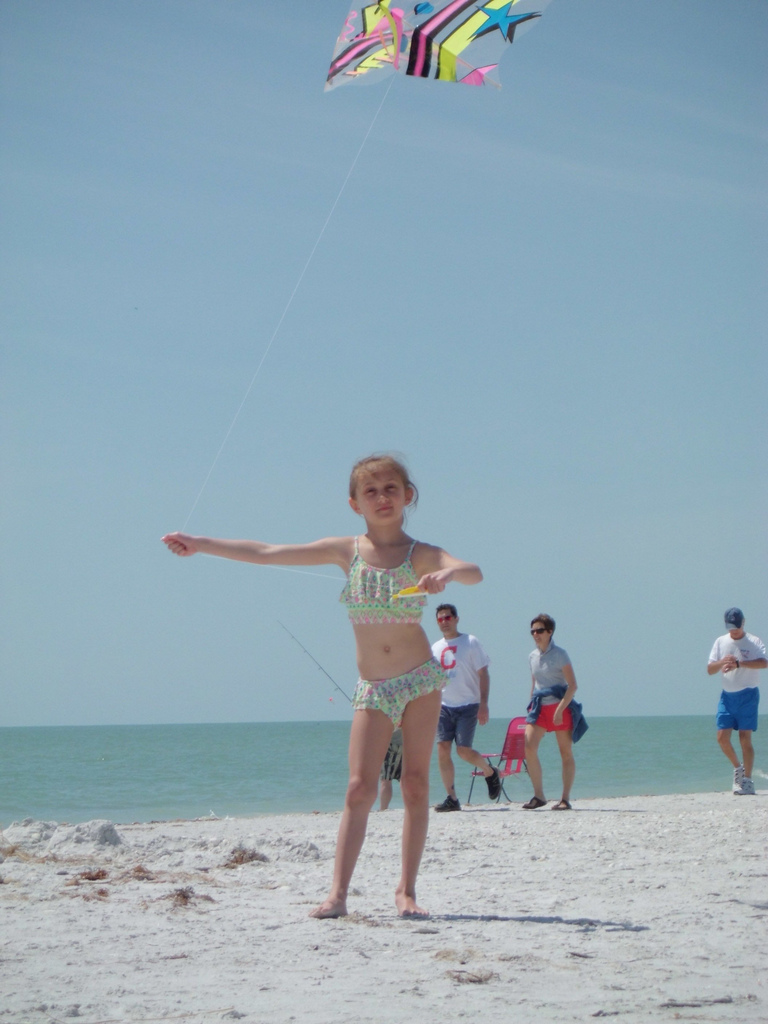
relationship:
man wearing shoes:
[430, 597, 498, 791] [430, 772, 506, 813]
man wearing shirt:
[714, 601, 764, 757] [428, 635, 485, 709]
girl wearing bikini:
[136, 441, 494, 915] [333, 539, 452, 717]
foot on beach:
[310, 894, 349, 921] [2, 777, 756, 1021]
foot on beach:
[392, 891, 427, 921] [2, 777, 756, 1021]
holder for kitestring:
[390, 573, 434, 612] [202, 543, 432, 607]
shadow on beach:
[339, 899, 668, 954] [2, 777, 756, 1021]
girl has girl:
[345, 453, 417, 531] [349, 454, 420, 509]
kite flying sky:
[324, 4, 539, 91] [3, 3, 764, 718]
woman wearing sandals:
[496, 606, 602, 830] [516, 797, 570, 812]